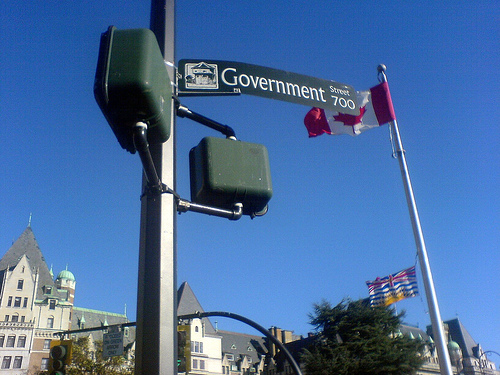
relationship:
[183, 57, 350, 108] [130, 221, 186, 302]
sign on pole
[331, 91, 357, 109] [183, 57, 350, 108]
numbers on sign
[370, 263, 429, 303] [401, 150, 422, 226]
flag on pole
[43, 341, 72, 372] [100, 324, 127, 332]
lights on pole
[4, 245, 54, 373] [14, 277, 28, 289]
building has window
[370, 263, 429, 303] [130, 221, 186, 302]
flag on pole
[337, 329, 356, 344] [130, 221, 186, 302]
tree by pole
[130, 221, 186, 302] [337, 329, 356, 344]
pole by tree